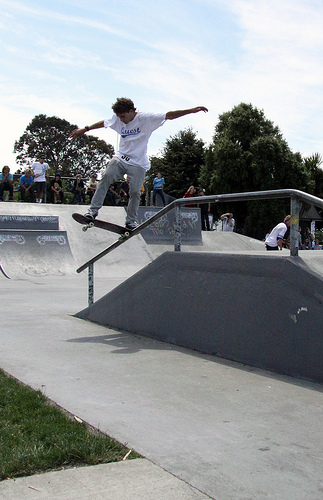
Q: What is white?
A: Shirt.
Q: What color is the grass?
A: Green.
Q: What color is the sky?
A: Blue.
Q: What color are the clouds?
A: White.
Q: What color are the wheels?
A: White.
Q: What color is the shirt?
A: White.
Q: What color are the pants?
A: Gray.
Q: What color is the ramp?
A: Gray.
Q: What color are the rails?
A: Gray.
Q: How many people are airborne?
A: One.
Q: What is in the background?
A: Trees.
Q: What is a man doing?
A: Skateboarding.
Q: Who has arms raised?
A: The skateboarder.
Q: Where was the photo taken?
A: At a skateboard park.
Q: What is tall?
A: Trees.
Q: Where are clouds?
A: In the sky.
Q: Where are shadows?
A: On the ground.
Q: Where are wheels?
A: On the skateboard.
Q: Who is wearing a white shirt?
A: Skateboarder.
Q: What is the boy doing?
A: Grinding.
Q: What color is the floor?
A: Grey.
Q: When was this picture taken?
A: Daytime.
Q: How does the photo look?
A: It looks clear.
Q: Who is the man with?
A: With friends.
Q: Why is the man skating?
A: To have fun.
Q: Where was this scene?
A: In a skatepark.